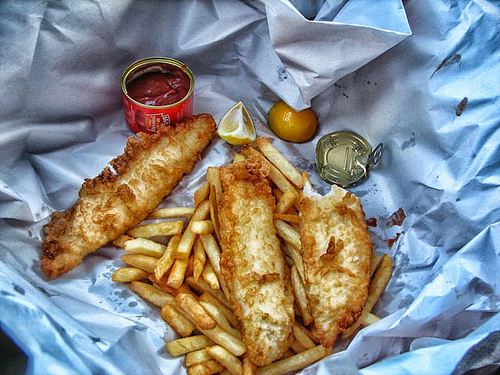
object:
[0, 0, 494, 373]
fabric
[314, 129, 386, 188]
lid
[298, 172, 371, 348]
fish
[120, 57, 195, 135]
can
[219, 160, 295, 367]
fish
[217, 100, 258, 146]
lemon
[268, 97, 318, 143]
yellow lemon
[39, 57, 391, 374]
food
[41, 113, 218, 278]
fish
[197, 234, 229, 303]
fries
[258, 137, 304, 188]
french fry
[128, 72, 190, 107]
red substance